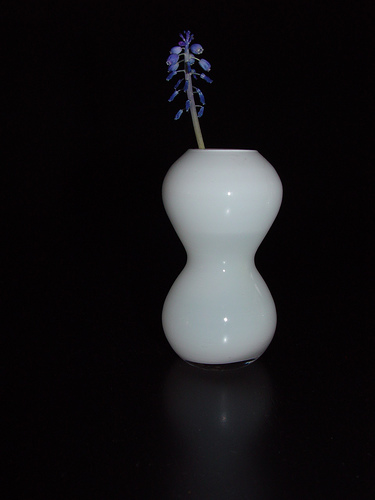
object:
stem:
[184, 46, 206, 150]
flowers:
[173, 109, 183, 121]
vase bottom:
[181, 356, 251, 370]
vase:
[159, 148, 284, 372]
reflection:
[161, 364, 274, 500]